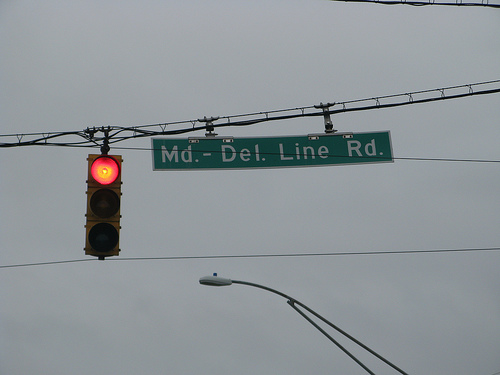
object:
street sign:
[150, 128, 394, 172]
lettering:
[160, 136, 383, 164]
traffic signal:
[82, 153, 124, 260]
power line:
[0, 246, 499, 269]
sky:
[1, 0, 499, 375]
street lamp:
[198, 272, 408, 374]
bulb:
[90, 188, 120, 217]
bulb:
[87, 223, 119, 251]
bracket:
[306, 102, 355, 141]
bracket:
[97, 126, 115, 155]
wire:
[0, 79, 500, 149]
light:
[212, 272, 219, 278]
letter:
[160, 143, 179, 163]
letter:
[221, 144, 236, 163]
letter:
[347, 139, 363, 158]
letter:
[302, 145, 317, 160]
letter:
[278, 141, 294, 161]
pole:
[232, 279, 408, 375]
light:
[91, 157, 119, 186]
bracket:
[187, 116, 236, 144]